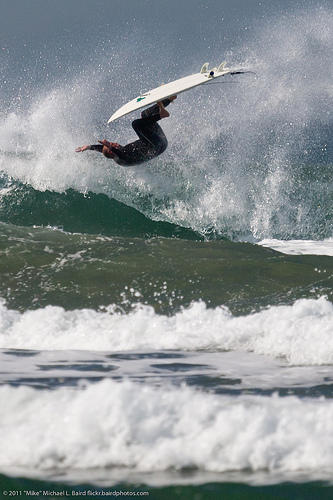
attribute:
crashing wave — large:
[193, 106, 283, 234]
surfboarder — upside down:
[73, 94, 180, 168]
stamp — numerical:
[8, 489, 23, 497]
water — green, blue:
[1, 10, 331, 498]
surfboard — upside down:
[103, 63, 264, 127]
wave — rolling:
[183, 100, 329, 244]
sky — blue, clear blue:
[0, 1, 331, 123]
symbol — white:
[0, 489, 11, 498]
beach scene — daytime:
[2, 2, 331, 489]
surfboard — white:
[102, 56, 258, 125]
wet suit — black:
[73, 94, 181, 168]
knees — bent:
[127, 108, 155, 137]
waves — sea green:
[8, 225, 331, 306]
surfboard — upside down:
[107, 61, 250, 125]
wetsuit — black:
[87, 96, 170, 168]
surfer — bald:
[76, 97, 176, 167]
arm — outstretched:
[99, 137, 128, 163]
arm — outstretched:
[74, 142, 104, 152]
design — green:
[132, 89, 148, 104]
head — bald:
[98, 139, 122, 159]